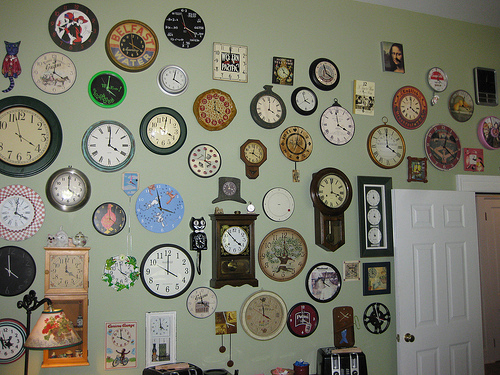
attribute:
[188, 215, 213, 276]
clock — black cat, shape of cat, cat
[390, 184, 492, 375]
door — open, white, ajar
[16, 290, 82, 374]
lamp — black, antique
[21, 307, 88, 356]
shade — floral, flower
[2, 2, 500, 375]
wall — of clocks, assortment, clocks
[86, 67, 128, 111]
clock — round, green, bright green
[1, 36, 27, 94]
cat — gray, blue, clock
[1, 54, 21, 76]
shirt — red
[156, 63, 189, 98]
clock — silver, tiny, small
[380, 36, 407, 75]
picture — mona lisa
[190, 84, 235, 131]
clock — brown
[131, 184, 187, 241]
clock — round, blue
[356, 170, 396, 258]
clocks — rectangular, three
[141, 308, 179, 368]
clocks — rectangular, white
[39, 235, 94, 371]
clocks — rectangular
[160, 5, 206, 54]
clock — black, round, white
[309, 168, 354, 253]
clock — using roman numerals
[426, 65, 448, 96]
clock — small, round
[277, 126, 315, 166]
clock — brown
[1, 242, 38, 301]
clock — black, circle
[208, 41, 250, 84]
clock — squared, square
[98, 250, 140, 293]
clock — with plants, small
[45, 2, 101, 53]
clock — round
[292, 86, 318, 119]
clock — red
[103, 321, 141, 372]
clock — curious george